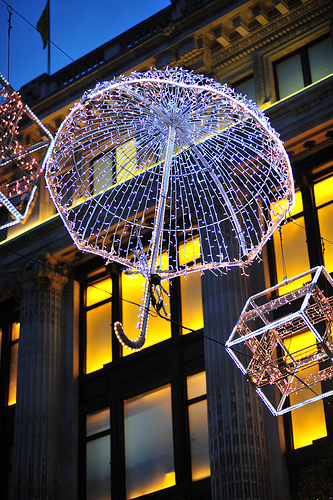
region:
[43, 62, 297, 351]
Umbrella lined with lights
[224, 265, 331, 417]
Illuminated frame of a box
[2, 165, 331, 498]
Backlit windows in the evening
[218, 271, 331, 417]
Suspended box with christmas lights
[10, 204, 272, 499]
cement pillars on building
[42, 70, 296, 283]
Blue christmas lights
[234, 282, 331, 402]
red christmas lights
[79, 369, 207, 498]
window with three panes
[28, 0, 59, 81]
flag on top of building at night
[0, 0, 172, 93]
Twilight sky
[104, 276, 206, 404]
Light on the building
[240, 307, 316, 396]
Metal grills on the photo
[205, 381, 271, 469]
Pillars on the building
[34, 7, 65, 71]
Flag on the building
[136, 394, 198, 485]
Illuminated building in the photo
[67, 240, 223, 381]
A building in the photo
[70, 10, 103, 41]
Blue skies in the photo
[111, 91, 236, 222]
Umbrella shaped metal railings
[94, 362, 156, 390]
Wall of a building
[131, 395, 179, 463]
Glass panes on the window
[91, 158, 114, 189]
glass window on building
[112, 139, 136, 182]
glass window on building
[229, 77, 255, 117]
glass window on building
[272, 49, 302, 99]
glass window on building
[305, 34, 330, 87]
glass window on building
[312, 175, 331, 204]
glass window on building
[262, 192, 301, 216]
glass window on building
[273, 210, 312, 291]
glass window on building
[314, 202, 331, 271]
glass window on building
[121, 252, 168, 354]
glass window on building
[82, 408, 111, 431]
glass window on building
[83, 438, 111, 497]
glass window on building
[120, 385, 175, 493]
glass window on building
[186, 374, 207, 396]
glass window on building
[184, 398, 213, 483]
glass window on building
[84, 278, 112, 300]
glass window on building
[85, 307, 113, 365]
glass window on building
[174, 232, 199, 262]
glass window on building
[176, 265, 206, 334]
glass window on building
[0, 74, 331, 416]
Aluminum structures suspended on wires covered in Christmas lights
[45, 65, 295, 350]
An aluminum structure resembling an umbrella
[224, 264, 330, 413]
An aluminum structure resembling a cube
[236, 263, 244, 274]
Christmas lights attached to a metal structure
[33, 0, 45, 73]
A flag at the top of a tall building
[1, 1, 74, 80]
Metal wires suspending objects in front of a building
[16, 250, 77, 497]
A white pillar on the facade of a building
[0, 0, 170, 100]
A dark blue evening's sky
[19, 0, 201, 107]
A small, decorative fence on top of a building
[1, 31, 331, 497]
Many windows on the front of a building